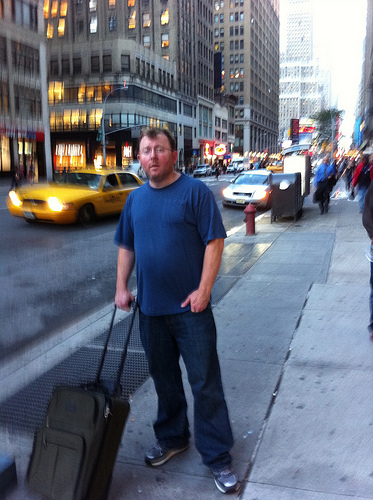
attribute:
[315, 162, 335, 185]
shirt — blue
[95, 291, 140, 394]
handle — long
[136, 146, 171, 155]
glasses — thin framed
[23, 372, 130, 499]
suitcase — brown, black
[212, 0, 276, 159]
building — tall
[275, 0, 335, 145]
building — tall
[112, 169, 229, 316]
t-shirt — blue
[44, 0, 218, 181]
building — tall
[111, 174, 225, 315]
shirt — blue, hort sleeved blue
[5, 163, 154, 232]
cab — yellow, taxi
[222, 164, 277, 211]
car — small, silver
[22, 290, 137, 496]
suitcase — black,  black rolling 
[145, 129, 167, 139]
peak — widows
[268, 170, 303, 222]
stand — black, newspaper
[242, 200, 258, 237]
hydrant — fire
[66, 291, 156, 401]
handle — black suitcase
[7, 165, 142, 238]
cab — yellow taxi 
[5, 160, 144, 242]
cab — moving taxi 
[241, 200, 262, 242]
hydrant — red fire  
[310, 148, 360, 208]
people — crowd 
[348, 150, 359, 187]
jacket — red 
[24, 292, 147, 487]
suitcase — black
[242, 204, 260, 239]
hydrant — fire, red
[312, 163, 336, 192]
shirt — blue 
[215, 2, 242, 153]
building — wall, side